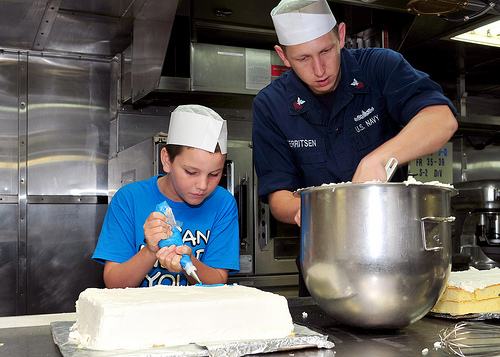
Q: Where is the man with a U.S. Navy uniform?
A: Standing near the silver bowl.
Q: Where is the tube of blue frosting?
A: In the boy's hands.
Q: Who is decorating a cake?
A: The boy in a blue shirt.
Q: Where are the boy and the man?
A: Inside of a kitchen.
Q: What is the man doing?
A: Scraping down a bowl.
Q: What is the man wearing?
A: A blue Navy uniform and a hat.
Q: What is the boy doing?
A: Decorating a cake.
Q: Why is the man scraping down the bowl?
A: To collect the rest of the frosting.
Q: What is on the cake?
A: White frosting.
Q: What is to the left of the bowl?
A: A partially frosted cake.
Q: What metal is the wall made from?
A: Steel.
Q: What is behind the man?
A: An oven.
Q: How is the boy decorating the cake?
A: With a tube of blue icing.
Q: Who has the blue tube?
A: The boy.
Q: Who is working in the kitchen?
A: A man and a boy.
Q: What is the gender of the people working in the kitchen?
A: Male.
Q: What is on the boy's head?
A: Hat.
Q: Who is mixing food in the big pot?
A: A man.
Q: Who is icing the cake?
A: A boy.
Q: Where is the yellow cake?
A: Beside the big mixing bowl.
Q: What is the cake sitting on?
A: Aluminum foil.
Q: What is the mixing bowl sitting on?
A: A countertop.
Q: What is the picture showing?
A: People decorating a cake.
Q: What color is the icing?
A: White.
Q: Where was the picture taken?
A: In a kitchen.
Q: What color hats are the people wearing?
A: White.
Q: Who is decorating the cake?
A: A boy.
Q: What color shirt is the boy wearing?
A: Blue.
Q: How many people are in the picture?
A: Two.